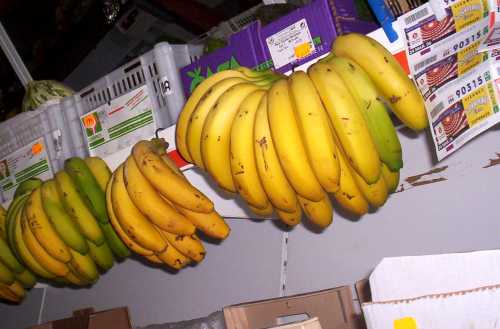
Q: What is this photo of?
A: Bananas.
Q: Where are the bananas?
A: In a store.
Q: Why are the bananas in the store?
A: For sale.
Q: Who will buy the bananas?
A: Customers.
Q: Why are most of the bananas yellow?
A: They are ripe.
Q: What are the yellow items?
A: Bunches of bananas.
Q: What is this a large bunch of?
A: Bananas.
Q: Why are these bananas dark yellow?
A: They are ripe.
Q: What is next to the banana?
A: A paper.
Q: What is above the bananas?
A: A purple box.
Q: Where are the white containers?
A: Above the bananas.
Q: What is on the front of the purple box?
A: A white sticker.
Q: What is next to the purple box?
A: A white crate.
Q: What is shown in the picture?
A: A market stand.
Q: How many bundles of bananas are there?
A: Four.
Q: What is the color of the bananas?
A: Yellow.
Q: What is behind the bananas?
A: Crates.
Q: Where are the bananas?
A: Hanging of the front.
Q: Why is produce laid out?
A: For sale.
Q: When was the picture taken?
A: At night.